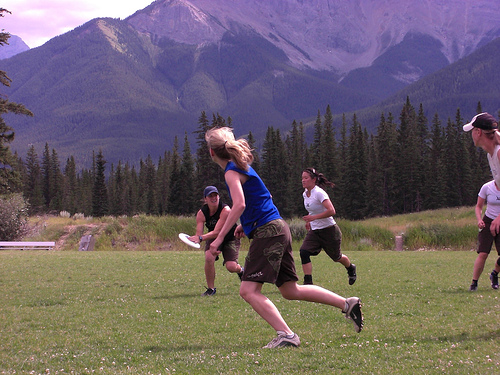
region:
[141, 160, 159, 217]
evergreen tree along the field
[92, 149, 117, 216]
evergreen tree along the field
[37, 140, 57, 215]
evergreen tree along the field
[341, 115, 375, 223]
evergreen tree along the field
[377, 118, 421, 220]
evergreen tree along the field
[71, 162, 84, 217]
evergreen tree along the field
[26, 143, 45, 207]
evergreen tree along the field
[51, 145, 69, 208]
evergreen tree along the field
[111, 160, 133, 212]
evergreen tree along the field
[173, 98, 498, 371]
a group of women playing a game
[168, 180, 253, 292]
she just caught the frisbee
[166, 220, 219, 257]
the frisbee is white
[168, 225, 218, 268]
the disk is white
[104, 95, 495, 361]
the women are playing a game in a large open field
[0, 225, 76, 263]
here is a metal bench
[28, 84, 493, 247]
the trees are very tall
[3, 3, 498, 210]
the mountains are covered in trees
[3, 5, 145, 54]
the sky is very hazy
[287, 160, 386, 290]
this woman is wearing a white top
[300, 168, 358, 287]
woman is wearing a white t shirt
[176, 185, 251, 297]
woman catching a frisbee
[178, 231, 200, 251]
frisbee is flat and white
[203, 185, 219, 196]
woman wearing a blue cap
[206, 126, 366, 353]
woman running in a field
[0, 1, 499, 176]
tall mountains behind field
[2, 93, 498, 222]
pine trees in front of mountains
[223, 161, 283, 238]
woman wearing a blue shirt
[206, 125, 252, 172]
blond hair in ponytail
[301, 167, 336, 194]
dark hair in ponytail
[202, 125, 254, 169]
Woman with blond hair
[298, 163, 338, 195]
Woman with dark hair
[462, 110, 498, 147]
Woman with black and white hat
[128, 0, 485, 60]
Mountain range topped with snow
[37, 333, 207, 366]
Green grass with white clover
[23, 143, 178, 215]
Several dark pine trees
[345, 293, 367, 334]
Black and white cletes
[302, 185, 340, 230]
White short sleeve shirt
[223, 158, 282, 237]
Blue sleeveless shirt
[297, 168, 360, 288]
Woman running in field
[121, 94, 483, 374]
women playing ultimate frisbee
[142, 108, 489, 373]
playing frisbee in a park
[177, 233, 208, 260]
the disc is white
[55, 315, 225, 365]
the grass is green and has small flowers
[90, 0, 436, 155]
the mountains are large and covered in trees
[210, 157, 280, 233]
her shirt is blue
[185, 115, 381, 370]
the woman has blonde hair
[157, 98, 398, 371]
the woman is wearing cleats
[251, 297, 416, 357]
these are Nike branded cleats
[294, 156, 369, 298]
she is Asian